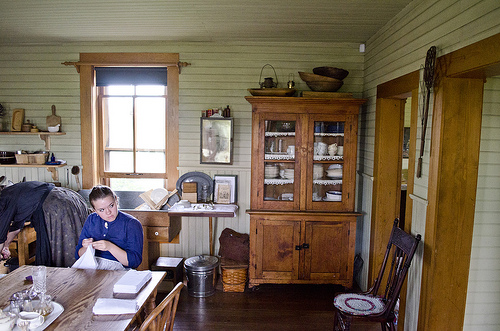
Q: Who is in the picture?
A: A woman.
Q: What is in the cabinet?
A: Dishes.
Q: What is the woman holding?
A: Fabric.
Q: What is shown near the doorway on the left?
A: Chair.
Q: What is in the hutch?
A: Dishes.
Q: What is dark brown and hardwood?
A: Floor.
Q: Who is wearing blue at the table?
A: Girl.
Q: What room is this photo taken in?
A: Dining room.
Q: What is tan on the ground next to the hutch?
A: Basket.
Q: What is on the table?
A: Napkins.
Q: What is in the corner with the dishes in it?
A: Hutch.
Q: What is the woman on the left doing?
A: Leaning.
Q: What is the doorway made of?
A: Wood.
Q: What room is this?
A: Kitchen.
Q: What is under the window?
A: Kitchen sink.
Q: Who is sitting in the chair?
A: A lady.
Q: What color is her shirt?
A: Blue.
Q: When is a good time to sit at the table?
A: To eat.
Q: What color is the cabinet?
A: Brown.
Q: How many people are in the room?
A: One.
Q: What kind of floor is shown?
A: Hardwood.